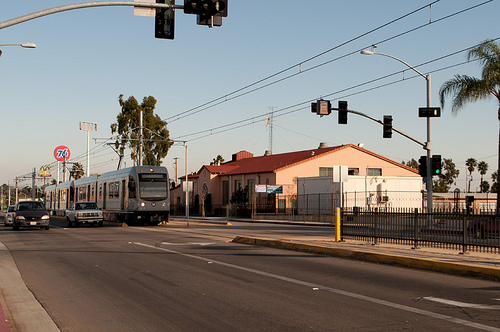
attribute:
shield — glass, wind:
[137, 170, 171, 202]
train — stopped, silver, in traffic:
[109, 140, 178, 212]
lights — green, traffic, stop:
[276, 88, 425, 148]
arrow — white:
[162, 206, 228, 269]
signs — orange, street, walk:
[247, 145, 292, 202]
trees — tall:
[439, 36, 490, 119]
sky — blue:
[86, 32, 315, 155]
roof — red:
[231, 139, 312, 193]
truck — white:
[66, 183, 109, 242]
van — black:
[17, 193, 53, 235]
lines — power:
[252, 37, 392, 99]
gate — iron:
[343, 171, 438, 257]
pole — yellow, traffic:
[332, 195, 359, 248]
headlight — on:
[134, 195, 159, 215]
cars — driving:
[3, 175, 84, 245]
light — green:
[431, 158, 453, 186]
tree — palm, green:
[439, 53, 498, 152]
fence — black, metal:
[349, 188, 449, 235]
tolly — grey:
[65, 145, 177, 197]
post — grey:
[397, 127, 453, 217]